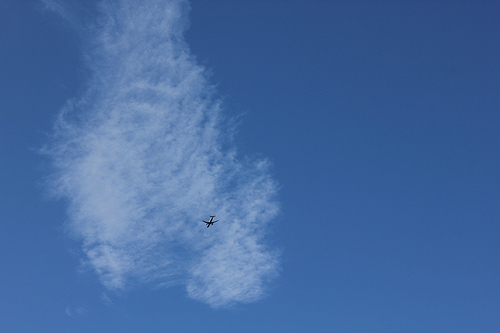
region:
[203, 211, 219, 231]
this is a plane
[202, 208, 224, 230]
the plane is on air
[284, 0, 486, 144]
the sky is blue in color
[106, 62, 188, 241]
the clouds are white in color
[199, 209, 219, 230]
the plane is black in color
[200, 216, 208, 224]
the wing is side apart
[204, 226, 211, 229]
the head is streamlined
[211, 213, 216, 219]
the tail is sharp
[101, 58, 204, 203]
the clouds are feathery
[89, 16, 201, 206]
the clouds are in one place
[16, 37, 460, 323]
An airplane soaring through a cloud.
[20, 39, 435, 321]
An airplane flying.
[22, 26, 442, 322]
An airplane flying in a blue sky.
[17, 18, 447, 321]
An airplane flying through a sky with one visible cloud.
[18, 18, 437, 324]
An airplane getting ready to land.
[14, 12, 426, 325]
A puffy cloud with an airplane flying through it.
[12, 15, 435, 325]
A dissipating cloud with an airplane flying through it.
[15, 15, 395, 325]
A big blue sky with an airplane and a cloud.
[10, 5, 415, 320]
An airplane flying under a cloud.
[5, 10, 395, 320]
An airplane flying next to a cloud.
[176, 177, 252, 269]
Commercial jet in the sky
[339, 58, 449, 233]
Blue sky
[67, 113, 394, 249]
Clouds in the blue sky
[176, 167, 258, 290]
Airplane flying through the sky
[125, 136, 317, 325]
The airplane with people in the air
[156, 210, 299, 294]
People traveling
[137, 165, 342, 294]
Traveling in the air for vacation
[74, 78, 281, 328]
Cloud in the sky with a plane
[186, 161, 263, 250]
Jet in the air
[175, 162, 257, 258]
Jet plane in the sky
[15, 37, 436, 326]
There is one plane in the sky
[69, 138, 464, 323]
There is only one plane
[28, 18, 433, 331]
The sky is blue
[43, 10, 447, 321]
There are clouds in the sky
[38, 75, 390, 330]
The plane is flying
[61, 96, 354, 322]
The clouds are over the plane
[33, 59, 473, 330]
The photo was taken during the day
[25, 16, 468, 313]
The photo was taken in the daytime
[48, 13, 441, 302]
There is only one plane flying in the photo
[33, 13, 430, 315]
There are clouds in the blue sky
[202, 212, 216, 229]
Airplane in the sky.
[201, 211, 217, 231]
Plane in the sky.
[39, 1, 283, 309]
Large wispy cloud in the sky.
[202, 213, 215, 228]
Airplane flying through clouds.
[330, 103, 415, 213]
Dark blue sky.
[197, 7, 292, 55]
Blue sky by the cloud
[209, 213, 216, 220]
Tail end of an airplane in the sky.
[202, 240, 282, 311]
Thin part of a large cloud in the sky.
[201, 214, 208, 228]
Airplane wing.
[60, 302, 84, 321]
Small thin cloud in the blue sky.